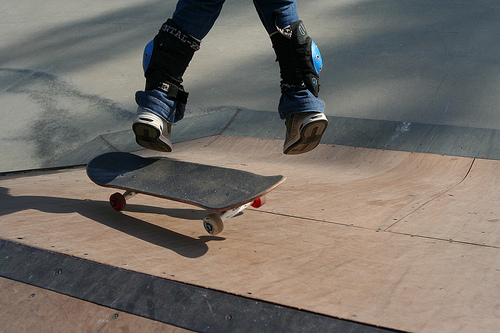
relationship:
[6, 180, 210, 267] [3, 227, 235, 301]
shadow on ground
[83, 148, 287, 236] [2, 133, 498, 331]
skateboard on ground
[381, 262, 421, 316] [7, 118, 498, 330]
black mark on ramp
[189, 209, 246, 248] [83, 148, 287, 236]
wheel on skateboard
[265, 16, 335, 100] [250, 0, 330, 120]
pad on leg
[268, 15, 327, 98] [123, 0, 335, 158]
shin guard on person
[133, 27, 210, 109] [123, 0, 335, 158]
shin guard on person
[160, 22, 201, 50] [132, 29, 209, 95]
letters on pad